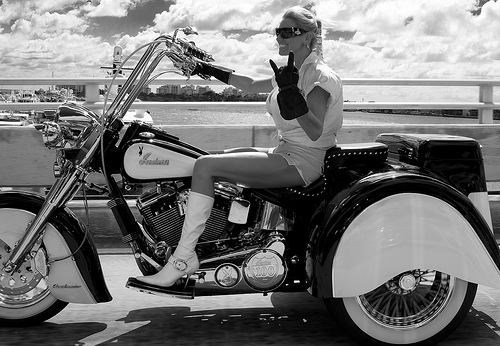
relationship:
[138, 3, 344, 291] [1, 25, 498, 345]
woman riding motorcycle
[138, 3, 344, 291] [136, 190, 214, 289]
woman wearing boot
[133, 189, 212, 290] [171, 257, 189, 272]
white boot with buckle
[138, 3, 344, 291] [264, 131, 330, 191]
woman wearing shorts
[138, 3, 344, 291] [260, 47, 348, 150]
woman wearing shirt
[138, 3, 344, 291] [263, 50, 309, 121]
woman wearing black gloves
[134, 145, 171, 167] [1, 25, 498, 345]
logo on motorcycle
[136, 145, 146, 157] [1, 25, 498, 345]
logo on motorcycle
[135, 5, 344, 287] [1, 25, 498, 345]
girl riding motorcycle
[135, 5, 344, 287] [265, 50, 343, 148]
girl with shirt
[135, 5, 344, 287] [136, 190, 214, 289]
girl with boot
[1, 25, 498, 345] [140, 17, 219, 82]
motorcycle has handlebars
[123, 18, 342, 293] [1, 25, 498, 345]
lady riding on a motorcycle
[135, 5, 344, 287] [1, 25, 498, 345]
girl on motorcycle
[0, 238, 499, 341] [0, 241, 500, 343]
tarmac on road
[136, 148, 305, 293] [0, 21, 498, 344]
leg on biker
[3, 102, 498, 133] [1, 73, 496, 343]
water behind bridge